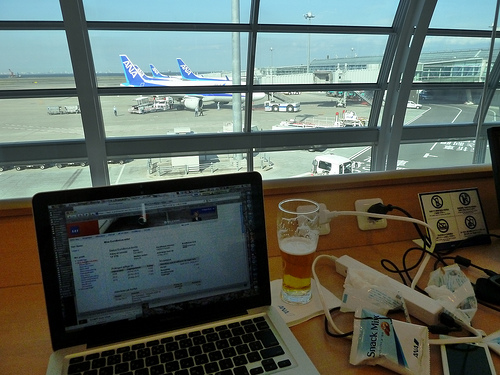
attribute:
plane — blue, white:
[115, 51, 263, 105]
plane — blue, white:
[175, 57, 265, 101]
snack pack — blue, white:
[346, 308, 432, 374]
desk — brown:
[2, 160, 497, 373]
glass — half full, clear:
[273, 193, 323, 307]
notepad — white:
[262, 266, 347, 329]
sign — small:
[416, 187, 494, 253]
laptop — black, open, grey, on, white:
[29, 168, 329, 374]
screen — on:
[40, 179, 262, 340]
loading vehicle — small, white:
[259, 98, 301, 115]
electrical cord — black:
[367, 202, 456, 331]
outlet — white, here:
[352, 193, 391, 232]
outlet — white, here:
[298, 197, 334, 241]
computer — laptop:
[26, 165, 326, 375]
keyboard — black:
[55, 309, 284, 372]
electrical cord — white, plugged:
[316, 203, 440, 296]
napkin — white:
[263, 269, 342, 331]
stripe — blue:
[266, 104, 299, 111]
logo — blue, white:
[124, 61, 139, 82]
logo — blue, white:
[182, 63, 192, 76]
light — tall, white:
[299, 5, 316, 77]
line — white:
[425, 99, 464, 160]